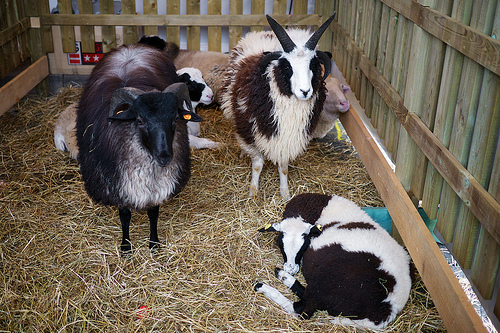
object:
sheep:
[317, 72, 357, 144]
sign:
[68, 42, 109, 65]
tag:
[180, 113, 194, 122]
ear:
[179, 108, 203, 123]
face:
[278, 46, 323, 102]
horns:
[161, 81, 195, 115]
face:
[131, 90, 182, 169]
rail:
[332, 0, 498, 333]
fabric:
[361, 205, 394, 233]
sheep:
[174, 50, 235, 111]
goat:
[252, 189, 413, 328]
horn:
[262, 13, 299, 50]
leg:
[267, 284, 303, 320]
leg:
[280, 270, 305, 297]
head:
[254, 217, 325, 276]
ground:
[0, 70, 449, 333]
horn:
[261, 8, 296, 52]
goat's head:
[257, 12, 342, 103]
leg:
[243, 154, 271, 201]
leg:
[273, 161, 296, 205]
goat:
[220, 11, 340, 202]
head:
[105, 82, 204, 168]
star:
[79, 51, 91, 64]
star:
[91, 51, 102, 61]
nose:
[302, 90, 309, 97]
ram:
[73, 33, 201, 254]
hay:
[0, 74, 449, 333]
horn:
[300, 11, 340, 50]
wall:
[335, 92, 494, 333]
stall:
[0, 0, 500, 333]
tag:
[259, 218, 270, 232]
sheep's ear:
[252, 222, 278, 233]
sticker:
[66, 37, 112, 65]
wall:
[45, 50, 329, 75]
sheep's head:
[323, 76, 352, 115]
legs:
[111, 202, 134, 256]